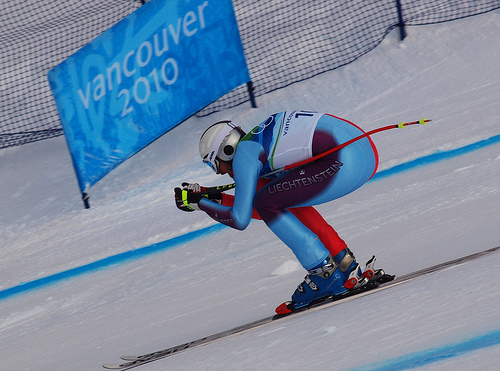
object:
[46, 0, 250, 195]
sign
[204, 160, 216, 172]
lenses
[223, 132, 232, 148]
strap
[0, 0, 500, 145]
fence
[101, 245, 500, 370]
snowboot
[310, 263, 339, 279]
buckles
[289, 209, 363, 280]
pant leg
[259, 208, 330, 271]
pant leg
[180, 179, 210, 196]
mans hand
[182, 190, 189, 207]
strap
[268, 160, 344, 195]
word liechtenstein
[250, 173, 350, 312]
leg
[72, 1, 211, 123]
vancouver 2010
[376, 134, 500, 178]
line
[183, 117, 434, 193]
stick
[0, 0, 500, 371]
scene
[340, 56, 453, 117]
slope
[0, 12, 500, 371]
day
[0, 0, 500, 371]
snow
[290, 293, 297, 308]
edge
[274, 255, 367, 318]
shoe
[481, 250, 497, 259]
slide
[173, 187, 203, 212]
glove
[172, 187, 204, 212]
hand